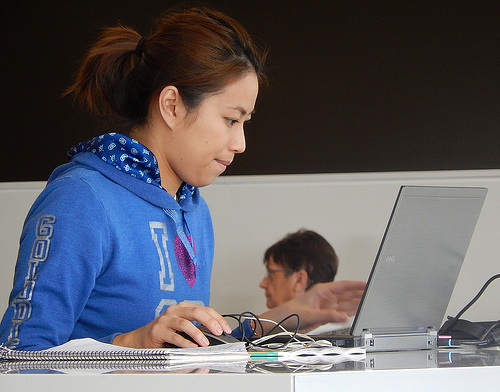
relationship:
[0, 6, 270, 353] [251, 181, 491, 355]
girl working on laptop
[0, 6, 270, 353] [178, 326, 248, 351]
girl has mouse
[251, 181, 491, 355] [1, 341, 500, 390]
laptop on table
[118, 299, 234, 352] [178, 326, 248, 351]
hand holding mouse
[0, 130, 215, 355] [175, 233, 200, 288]
shirt has heart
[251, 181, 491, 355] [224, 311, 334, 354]
laptop has cables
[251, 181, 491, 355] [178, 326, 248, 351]
laptop has mouse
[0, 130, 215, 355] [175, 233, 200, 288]
shirt has a heart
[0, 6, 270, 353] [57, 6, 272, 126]
girl has hair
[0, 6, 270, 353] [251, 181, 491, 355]
girl has laptop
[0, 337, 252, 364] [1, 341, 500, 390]
notebook on table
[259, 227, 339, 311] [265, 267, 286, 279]
person has glasses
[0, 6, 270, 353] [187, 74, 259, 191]
girl has a face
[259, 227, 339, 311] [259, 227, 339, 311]
person has person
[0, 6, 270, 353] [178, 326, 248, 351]
girl holding mouse